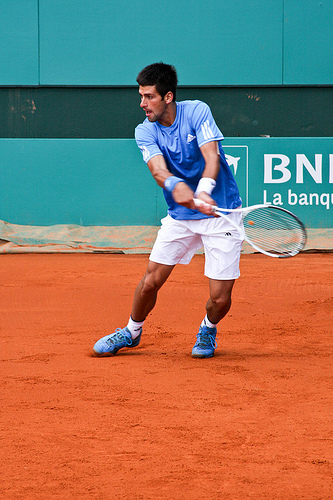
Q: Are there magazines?
A: No, there are no magazines.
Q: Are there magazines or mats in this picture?
A: No, there are no magazines or mats.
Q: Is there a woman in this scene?
A: No, there are no women.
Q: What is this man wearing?
A: The man is wearing a shoe.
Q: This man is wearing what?
A: The man is wearing a shoe.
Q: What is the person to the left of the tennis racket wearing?
A: The man is wearing a shoe.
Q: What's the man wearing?
A: The man is wearing a shoe.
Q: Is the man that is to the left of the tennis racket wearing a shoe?
A: Yes, the man is wearing a shoe.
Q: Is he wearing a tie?
A: No, the man is wearing a shoe.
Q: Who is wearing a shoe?
A: The man is wearing a shoe.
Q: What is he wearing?
A: The man is wearing a shoe.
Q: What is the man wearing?
A: The man is wearing a shoe.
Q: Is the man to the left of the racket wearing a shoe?
A: Yes, the man is wearing a shoe.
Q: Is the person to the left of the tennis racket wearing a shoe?
A: Yes, the man is wearing a shoe.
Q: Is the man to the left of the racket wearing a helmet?
A: No, the man is wearing a shoe.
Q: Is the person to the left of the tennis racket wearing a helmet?
A: No, the man is wearing a shoe.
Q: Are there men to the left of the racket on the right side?
A: Yes, there is a man to the left of the racket.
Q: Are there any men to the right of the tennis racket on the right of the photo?
A: No, the man is to the left of the tennis racket.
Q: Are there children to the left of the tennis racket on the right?
A: No, there is a man to the left of the tennis racket.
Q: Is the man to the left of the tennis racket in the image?
A: Yes, the man is to the left of the tennis racket.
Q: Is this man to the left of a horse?
A: No, the man is to the left of the tennis racket.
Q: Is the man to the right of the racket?
A: No, the man is to the left of the racket.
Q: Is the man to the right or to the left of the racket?
A: The man is to the left of the racket.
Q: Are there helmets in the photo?
A: No, there are no helmets.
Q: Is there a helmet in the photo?
A: No, there are no helmets.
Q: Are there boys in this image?
A: No, there are no boys.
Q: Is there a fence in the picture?
A: No, there are no fences.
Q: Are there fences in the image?
A: No, there are no fences.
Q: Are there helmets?
A: No, there are no helmets.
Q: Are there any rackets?
A: Yes, there is a racket.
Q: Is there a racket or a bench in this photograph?
A: Yes, there is a racket.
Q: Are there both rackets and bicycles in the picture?
A: No, there is a racket but no bicycles.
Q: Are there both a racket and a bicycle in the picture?
A: No, there is a racket but no bicycles.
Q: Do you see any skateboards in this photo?
A: No, there are no skateboards.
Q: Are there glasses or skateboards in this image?
A: No, there are no skateboards or glasses.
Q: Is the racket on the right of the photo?
A: Yes, the racket is on the right of the image.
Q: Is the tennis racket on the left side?
A: No, the tennis racket is on the right of the image.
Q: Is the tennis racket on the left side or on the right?
A: The tennis racket is on the right of the image.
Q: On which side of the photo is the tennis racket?
A: The tennis racket is on the right of the image.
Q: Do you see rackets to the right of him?
A: Yes, there is a racket to the right of the man.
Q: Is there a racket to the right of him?
A: Yes, there is a racket to the right of the man.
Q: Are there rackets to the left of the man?
A: No, the racket is to the right of the man.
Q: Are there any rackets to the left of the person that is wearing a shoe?
A: No, the racket is to the right of the man.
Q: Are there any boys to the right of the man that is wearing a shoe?
A: No, there is a racket to the right of the man.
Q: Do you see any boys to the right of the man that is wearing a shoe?
A: No, there is a racket to the right of the man.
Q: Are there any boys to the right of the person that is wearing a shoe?
A: No, there is a racket to the right of the man.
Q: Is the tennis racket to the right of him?
A: Yes, the tennis racket is to the right of a man.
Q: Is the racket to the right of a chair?
A: No, the racket is to the right of a man.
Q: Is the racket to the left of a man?
A: No, the racket is to the right of a man.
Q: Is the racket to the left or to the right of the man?
A: The racket is to the right of the man.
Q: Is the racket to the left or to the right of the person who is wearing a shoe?
A: The racket is to the right of the man.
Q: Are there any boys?
A: No, there are no boys.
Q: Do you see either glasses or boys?
A: No, there are no boys or glasses.